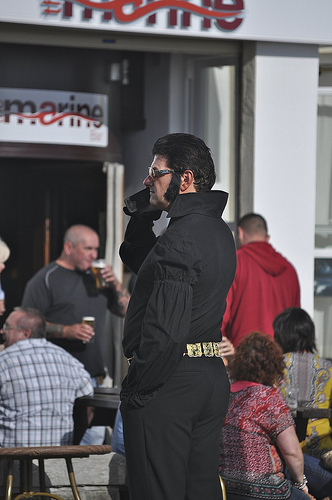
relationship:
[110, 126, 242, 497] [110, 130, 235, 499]
man wears elvis costume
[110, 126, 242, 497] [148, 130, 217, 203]
man has hair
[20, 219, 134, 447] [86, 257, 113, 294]
man holds beer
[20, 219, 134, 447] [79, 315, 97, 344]
man holds beer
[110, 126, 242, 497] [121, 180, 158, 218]
man holds cellphone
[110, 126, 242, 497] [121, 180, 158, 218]
man listens on cellphone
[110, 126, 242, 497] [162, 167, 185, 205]
man has sideburn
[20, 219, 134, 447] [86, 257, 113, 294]
man slips beer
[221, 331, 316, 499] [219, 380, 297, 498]
woman wears shirt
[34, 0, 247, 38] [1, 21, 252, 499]
sign above doorway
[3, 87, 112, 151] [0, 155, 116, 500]
sign above doorway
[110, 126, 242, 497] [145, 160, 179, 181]
man wears glasses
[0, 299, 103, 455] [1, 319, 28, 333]
man wears glasses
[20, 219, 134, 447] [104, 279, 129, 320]
man has forearm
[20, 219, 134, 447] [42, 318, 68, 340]
man has forearm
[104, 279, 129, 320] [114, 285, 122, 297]
forearm has tattoo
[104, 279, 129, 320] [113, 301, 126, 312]
forearm has tattoo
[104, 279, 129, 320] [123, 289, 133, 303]
forearm has tattoo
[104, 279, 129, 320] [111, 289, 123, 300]
forearm has tattoo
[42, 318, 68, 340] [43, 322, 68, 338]
forearm has tattoos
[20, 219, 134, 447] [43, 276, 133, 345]
man has tattoos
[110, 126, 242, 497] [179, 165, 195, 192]
man has ear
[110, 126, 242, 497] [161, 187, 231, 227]
man has collar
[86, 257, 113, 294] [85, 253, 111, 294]
beer in glass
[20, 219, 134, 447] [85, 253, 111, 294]
man drinks from glass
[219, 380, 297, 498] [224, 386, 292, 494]
shirt has print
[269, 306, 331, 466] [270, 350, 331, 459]
person wears shirt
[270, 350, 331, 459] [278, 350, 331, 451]
shirt has print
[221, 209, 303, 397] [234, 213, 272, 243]
person has buzz cut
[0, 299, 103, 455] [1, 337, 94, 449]
man wears shirt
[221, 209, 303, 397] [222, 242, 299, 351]
person wears hoodie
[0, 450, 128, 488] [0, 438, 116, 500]
concrete block behind furniture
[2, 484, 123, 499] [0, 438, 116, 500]
concrete block behind furniture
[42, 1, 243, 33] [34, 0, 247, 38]
printing on sign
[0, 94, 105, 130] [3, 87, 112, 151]
printing on sign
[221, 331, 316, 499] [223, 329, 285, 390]
woman has hair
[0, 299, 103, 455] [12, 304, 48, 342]
man has hair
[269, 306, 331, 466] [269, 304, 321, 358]
person has hair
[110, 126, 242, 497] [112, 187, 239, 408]
man wears shirt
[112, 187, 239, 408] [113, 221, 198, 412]
shirt has sleeve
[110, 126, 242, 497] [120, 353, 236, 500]
man wears pants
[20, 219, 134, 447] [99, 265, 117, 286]
man has hand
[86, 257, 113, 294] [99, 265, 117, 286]
beer in hand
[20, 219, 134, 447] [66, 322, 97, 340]
man has hand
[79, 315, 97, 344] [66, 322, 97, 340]
beer in hand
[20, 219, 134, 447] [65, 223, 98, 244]
man has bald spot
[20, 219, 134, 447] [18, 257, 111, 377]
man wears shirt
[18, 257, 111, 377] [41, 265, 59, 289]
shirt has seam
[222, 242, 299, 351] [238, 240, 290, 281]
hoodie has hood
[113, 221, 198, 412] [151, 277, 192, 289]
sleeve has elastic@top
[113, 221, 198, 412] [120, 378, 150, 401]
sleeve has elastic@wrist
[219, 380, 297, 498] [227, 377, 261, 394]
shirt has undershirt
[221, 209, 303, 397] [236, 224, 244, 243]
person has ear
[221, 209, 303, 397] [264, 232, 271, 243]
person has ear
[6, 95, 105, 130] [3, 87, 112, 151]
marine on sign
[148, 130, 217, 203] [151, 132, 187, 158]
hair has front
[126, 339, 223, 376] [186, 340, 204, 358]
belt has medallion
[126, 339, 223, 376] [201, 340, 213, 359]
belt has medallion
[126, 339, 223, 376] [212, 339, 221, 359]
belt has medallion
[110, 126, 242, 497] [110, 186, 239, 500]
man maybe wearing jumpsuit